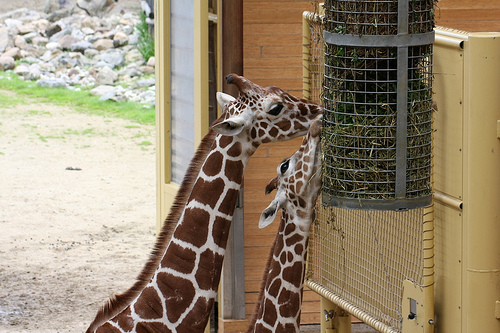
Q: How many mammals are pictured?
A: Two.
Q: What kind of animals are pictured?
A: Giraffes.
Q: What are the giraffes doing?
A: Eating grass.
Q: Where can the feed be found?
A: Cage.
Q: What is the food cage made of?
A: Metal.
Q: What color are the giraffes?
A: Brown and white.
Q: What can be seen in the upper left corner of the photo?
A: Rocks.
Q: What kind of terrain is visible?
A: Sandy and grassy.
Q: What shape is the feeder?
A: Cylindrical.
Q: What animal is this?
A: Giraffe.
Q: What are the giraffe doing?
A: Eating.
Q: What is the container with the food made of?
A: Metal.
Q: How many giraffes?
A: Two.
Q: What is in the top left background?
A: Rocks.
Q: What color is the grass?
A: Green.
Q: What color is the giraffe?
A: Brown and white.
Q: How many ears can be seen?
A: Four.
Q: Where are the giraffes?
A: Zoo.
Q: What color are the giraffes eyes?
A: Black.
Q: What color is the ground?
A: Light brown.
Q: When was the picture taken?
A: Daytime.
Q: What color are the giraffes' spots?
A: Brown.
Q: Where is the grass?
A: In a cage.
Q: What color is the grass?
A: Green.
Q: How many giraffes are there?
A: Two.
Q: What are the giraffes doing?
A: Eating.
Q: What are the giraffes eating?
A: Grass.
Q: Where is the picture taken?
A: At the zoo.